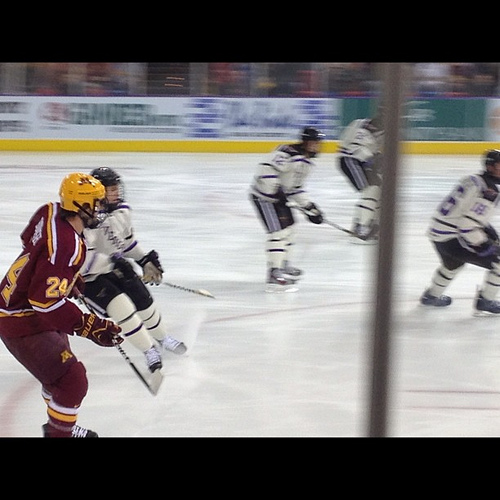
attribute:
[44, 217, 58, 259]
uniform — gold, maroon, white, black, blue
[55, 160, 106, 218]
helmet — yellow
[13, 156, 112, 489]
hockey player — skating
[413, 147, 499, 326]
player — skating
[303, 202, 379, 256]
hockey stick — white, black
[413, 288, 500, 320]
skates — black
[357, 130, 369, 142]
number 6 — black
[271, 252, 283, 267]
socks — white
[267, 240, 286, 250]
stripes — black, yellow, white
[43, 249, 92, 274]
jersey — red, gold, white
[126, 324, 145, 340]
stripes — blue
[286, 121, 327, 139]
helmet — black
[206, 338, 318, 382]
floor — white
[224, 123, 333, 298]
man — skating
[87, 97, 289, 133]
gate — white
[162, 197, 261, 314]
ice rink — big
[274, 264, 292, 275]
laces — white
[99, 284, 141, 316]
shin guards — white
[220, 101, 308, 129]
blackboard — white